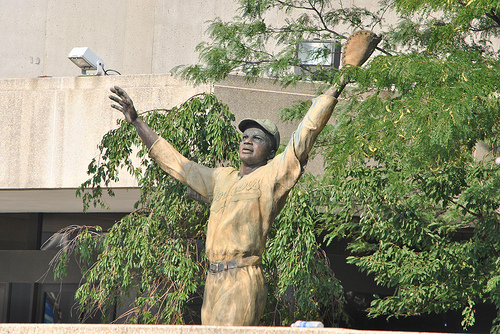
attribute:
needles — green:
[38, 211, 88, 274]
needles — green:
[143, 184, 194, 264]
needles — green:
[360, 245, 411, 315]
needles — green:
[362, 175, 442, 253]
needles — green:
[401, 97, 461, 178]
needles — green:
[179, 0, 301, 84]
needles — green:
[167, 95, 235, 154]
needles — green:
[383, 3, 453, 51]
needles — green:
[202, 19, 225, 36]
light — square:
[67, 43, 102, 73]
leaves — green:
[76, 180, 88, 198]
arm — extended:
[110, 83, 210, 203]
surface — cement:
[3, 80, 403, 199]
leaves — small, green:
[78, 238, 93, 264]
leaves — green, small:
[103, 126, 129, 167]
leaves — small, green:
[194, 99, 208, 111]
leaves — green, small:
[134, 294, 154, 302]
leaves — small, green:
[281, 254, 291, 274]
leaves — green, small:
[304, 192, 324, 205]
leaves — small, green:
[374, 215, 399, 246]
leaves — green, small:
[337, 112, 350, 129]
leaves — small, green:
[211, 66, 230, 79]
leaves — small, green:
[332, 69, 469, 219]